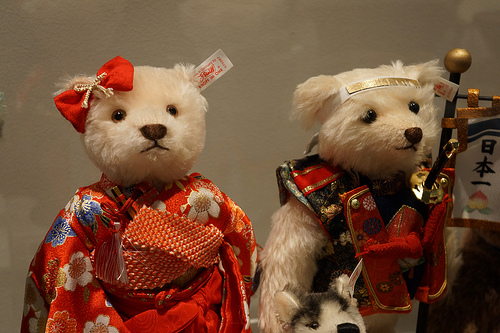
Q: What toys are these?
A: Teddy bears.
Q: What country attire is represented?
A: Japan.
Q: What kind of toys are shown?
A: Teddy bears.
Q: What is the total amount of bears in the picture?
A: 2.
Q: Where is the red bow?
A: In the hair of the bear on the left.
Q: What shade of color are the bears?
A: Tan.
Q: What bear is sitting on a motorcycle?
A: Neither.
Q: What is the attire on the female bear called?
A: A Kimono.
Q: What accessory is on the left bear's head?
A: A bow.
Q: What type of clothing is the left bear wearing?
A: A kimono.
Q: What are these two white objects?
A: Stuffed bears.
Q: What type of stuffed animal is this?
A: A bear.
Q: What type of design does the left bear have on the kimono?
A: Floral.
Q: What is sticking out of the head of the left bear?
A: A tag.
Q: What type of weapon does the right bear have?
A: A sword.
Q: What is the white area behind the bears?
A: A wall.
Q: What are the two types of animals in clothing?
A: Bears.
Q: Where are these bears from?
A: Japan.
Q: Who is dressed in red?
A: Teddy bear.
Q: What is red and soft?
A: Cloth.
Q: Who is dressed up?
A: Teddy bear.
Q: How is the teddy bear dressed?
A: In a kimono.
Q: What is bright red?
A: Bow.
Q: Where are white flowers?
A: On the kimono.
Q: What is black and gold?
A: The vest.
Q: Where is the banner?
A: On the pole.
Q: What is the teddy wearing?
A: Red dress.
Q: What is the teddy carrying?
A: Red cloth.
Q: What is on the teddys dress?
A: Flowers.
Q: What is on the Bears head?
A: A bow.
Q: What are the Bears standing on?
A: The floor.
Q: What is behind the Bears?
A: The wall.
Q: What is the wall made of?
A: Drywall.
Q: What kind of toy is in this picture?
A: Toy bears.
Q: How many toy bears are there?
A: Two.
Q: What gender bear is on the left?
A: Female.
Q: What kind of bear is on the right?
A: A soldier toy bear.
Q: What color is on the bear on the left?
A: Red.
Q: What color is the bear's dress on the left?
A: Red, blue and white.